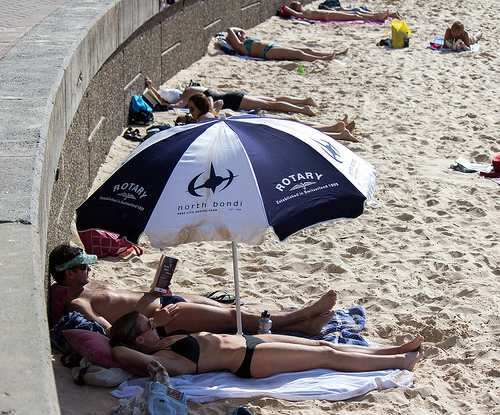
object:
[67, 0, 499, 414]
sand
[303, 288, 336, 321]
feet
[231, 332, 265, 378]
bikini bottom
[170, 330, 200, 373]
bikini top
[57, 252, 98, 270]
visor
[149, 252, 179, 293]
book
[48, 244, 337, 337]
man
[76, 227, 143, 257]
chair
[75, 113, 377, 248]
umbrella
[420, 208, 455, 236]
foot print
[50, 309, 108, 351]
jeans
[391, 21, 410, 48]
bag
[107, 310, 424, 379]
woman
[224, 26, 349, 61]
woman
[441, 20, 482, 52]
man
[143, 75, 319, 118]
woman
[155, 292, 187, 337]
speedo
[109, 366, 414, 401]
towel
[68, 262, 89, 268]
sunglasses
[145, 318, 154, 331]
sunglasses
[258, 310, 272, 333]
bottle